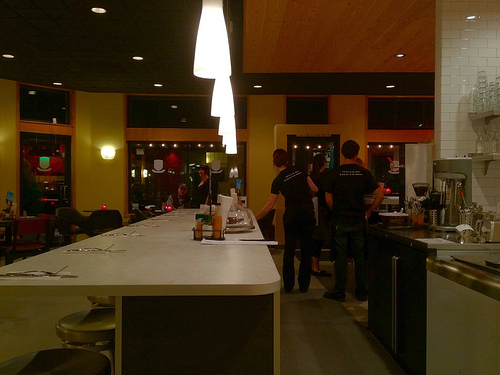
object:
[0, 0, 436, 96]
ceiling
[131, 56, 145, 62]
lights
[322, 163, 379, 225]
shirt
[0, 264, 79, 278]
utensils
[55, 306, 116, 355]
bar stool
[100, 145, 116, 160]
light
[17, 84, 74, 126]
windows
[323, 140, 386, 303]
bartender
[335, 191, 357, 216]
black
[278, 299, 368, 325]
shadow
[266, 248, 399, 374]
floor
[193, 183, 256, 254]
items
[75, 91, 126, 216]
wall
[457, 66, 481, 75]
tiles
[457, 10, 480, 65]
reflection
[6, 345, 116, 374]
bar stool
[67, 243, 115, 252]
silverware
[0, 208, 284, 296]
counter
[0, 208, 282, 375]
bar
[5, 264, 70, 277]
fork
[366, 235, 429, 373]
cabinet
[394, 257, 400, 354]
handles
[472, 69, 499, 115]
glasses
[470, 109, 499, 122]
shelf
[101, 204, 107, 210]
candle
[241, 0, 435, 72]
paneling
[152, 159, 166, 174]
design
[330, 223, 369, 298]
blue jeans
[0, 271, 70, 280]
napkins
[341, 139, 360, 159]
hair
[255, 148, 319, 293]
woman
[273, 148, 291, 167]
short hair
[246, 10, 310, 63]
wood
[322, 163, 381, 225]
back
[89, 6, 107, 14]
light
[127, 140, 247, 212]
window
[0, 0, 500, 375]
restaurant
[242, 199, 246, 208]
cups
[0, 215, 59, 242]
table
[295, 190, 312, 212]
black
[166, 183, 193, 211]
man